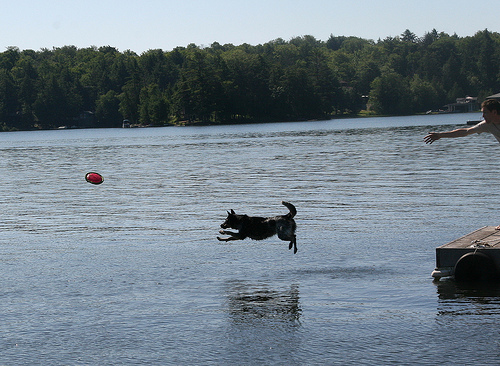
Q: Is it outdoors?
A: Yes, it is outdoors.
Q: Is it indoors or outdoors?
A: It is outdoors.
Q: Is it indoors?
A: No, it is outdoors.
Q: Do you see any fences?
A: No, there are no fences.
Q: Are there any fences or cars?
A: No, there are no fences or cars.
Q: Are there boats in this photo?
A: No, there are no boats.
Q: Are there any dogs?
A: Yes, there is a dog.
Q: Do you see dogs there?
A: Yes, there is a dog.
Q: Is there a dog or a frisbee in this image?
A: Yes, there is a dog.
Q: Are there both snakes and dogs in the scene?
A: No, there is a dog but no snakes.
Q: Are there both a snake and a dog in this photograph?
A: No, there is a dog but no snakes.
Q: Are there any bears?
A: No, there are no bears.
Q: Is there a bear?
A: No, there are no bears.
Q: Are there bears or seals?
A: No, there are no bears or seals.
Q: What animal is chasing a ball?
A: The dog is chasing a ball.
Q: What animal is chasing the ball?
A: The dog is chasing a ball.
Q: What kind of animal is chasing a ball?
A: The animal is a dog.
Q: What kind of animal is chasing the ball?
A: The animal is a dog.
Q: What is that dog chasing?
A: The dog is chasing a ball.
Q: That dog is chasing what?
A: The dog is chasing a ball.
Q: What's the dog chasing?
A: The dog is chasing a ball.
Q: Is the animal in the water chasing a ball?
A: Yes, the dog is chasing a ball.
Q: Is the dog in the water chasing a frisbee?
A: No, the dog is chasing a ball.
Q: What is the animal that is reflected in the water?
A: The animal is a dog.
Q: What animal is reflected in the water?
A: The animal is a dog.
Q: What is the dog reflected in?
A: The dog is reflected in the water.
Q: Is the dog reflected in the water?
A: Yes, the dog is reflected in the water.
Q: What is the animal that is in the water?
A: The animal is a dog.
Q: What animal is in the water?
A: The animal is a dog.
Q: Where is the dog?
A: The dog is in the water.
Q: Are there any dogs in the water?
A: Yes, there is a dog in the water.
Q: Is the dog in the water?
A: Yes, the dog is in the water.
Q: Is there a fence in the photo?
A: No, there are no fences.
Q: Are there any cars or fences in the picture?
A: No, there are no fences or cars.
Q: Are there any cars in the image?
A: No, there are no cars.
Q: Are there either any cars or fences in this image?
A: No, there are no cars or fences.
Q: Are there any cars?
A: No, there are no cars.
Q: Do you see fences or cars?
A: No, there are no cars or fences.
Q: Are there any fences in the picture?
A: No, there are no fences.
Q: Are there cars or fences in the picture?
A: No, there are no fences or cars.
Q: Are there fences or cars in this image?
A: No, there are no fences or cars.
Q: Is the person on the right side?
A: Yes, the person is on the right of the image.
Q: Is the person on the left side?
A: No, the person is on the right of the image.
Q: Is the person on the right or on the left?
A: The person is on the right of the image.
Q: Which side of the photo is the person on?
A: The person is on the right of the image.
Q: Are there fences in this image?
A: No, there are no fences.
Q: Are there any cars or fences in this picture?
A: No, there are no fences or cars.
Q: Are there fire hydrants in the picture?
A: No, there are no fire hydrants.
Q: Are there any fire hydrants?
A: No, there are no fire hydrants.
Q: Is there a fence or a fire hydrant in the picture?
A: No, there are no fire hydrants or fences.